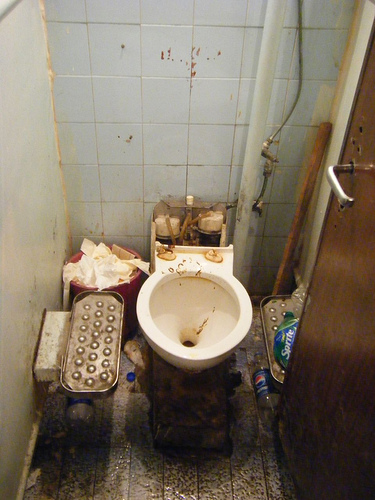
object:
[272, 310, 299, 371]
sprite bottle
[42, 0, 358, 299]
wall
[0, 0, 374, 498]
building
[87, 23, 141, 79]
wall tile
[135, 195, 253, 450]
toilet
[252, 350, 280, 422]
pepsi bottle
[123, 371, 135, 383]
bottle top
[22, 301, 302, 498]
ground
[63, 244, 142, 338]
trashcan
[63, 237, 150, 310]
trash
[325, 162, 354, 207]
handle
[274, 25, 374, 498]
door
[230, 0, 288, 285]
pipe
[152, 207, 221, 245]
inside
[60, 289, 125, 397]
stand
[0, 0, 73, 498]
wall